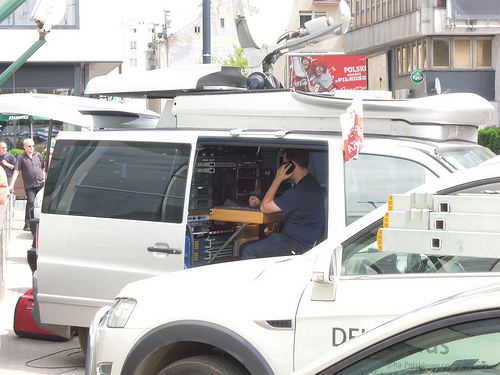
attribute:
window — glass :
[338, 149, 428, 207]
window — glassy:
[447, 35, 479, 69]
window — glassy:
[430, 39, 455, 66]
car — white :
[81, 150, 499, 373]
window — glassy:
[409, 41, 473, 71]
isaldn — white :
[169, 68, 186, 70]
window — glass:
[34, 141, 181, 227]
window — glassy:
[450, 35, 475, 68]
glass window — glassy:
[413, 40, 424, 71]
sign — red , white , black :
[286, 51, 371, 93]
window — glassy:
[16, 1, 98, 22]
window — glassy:
[400, 45, 406, 76]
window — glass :
[335, 317, 499, 373]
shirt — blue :
[252, 163, 329, 243]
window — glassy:
[395, 39, 425, 73]